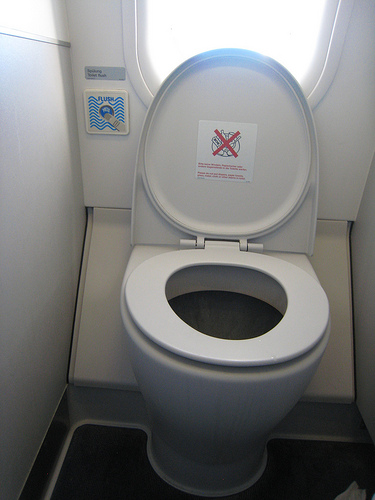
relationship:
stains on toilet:
[203, 395, 252, 465] [124, 42, 336, 497]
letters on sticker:
[214, 128, 239, 155] [197, 120, 258, 185]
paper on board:
[335, 480, 368, 499] [54, 378, 370, 499]